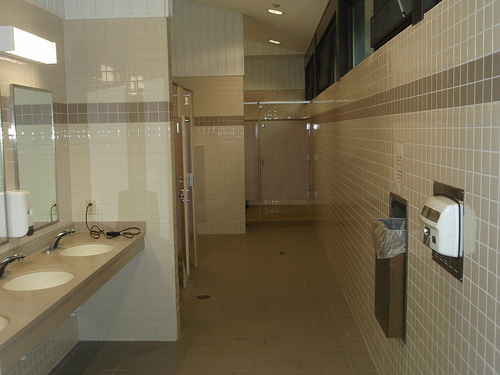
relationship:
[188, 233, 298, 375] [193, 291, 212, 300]
round floor drain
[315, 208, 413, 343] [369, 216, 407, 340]
waste receptacle with garbage can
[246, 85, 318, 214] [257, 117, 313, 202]
shower stall door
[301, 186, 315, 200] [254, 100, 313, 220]
hinge for shower stall door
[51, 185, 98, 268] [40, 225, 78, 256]
chrome colored bathroom faucet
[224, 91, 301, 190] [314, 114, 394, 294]
four inch tiled wall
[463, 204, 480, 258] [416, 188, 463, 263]
image of hand dryer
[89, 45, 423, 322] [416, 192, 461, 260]
bathroom with hand dryer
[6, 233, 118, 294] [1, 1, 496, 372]
sinks in bathroom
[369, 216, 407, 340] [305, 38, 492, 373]
garbage can on wall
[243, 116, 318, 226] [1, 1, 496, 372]
stall in bathroom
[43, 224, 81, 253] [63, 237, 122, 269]
faucet for sink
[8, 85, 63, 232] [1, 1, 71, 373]
mirror on wall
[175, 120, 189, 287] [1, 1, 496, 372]
door in bathroom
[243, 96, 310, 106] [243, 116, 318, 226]
pipe above stall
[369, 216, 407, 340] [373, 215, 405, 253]
garbage can with liner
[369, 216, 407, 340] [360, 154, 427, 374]
garbage can on wall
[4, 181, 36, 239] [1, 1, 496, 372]
soap dispenser in bathroom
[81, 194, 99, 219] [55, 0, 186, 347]
outlet in wall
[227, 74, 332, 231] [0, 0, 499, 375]
stall in bathroom